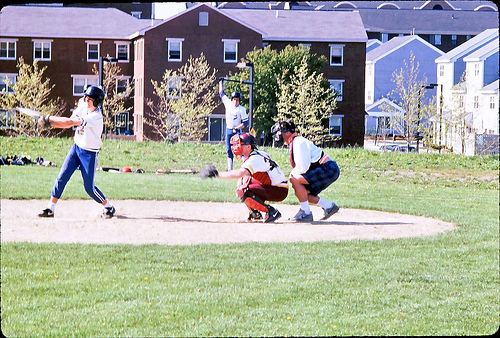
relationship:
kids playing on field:
[39, 77, 339, 222] [0, 136, 499, 337]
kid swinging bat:
[39, 86, 115, 218] [14, 103, 46, 122]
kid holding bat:
[218, 78, 249, 173] [218, 76, 256, 87]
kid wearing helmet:
[39, 86, 115, 218] [84, 85, 105, 105]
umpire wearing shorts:
[271, 121, 340, 223] [301, 160, 339, 196]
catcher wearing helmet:
[204, 132, 289, 225] [239, 132, 257, 147]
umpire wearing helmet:
[271, 121, 340, 223] [278, 121, 297, 133]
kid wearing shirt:
[39, 86, 115, 218] [73, 97, 103, 150]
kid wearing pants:
[39, 86, 115, 218] [48, 145, 107, 203]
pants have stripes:
[48, 145, 107, 203] [93, 188, 107, 203]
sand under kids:
[0, 199, 462, 246] [39, 77, 339, 222]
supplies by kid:
[0, 149, 197, 176] [218, 78, 249, 173]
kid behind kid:
[218, 78, 249, 173] [39, 86, 115, 218]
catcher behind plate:
[204, 132, 289, 225] [60, 212, 99, 222]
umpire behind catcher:
[271, 121, 340, 223] [204, 132, 289, 225]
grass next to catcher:
[0, 165, 498, 335] [204, 132, 289, 225]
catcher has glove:
[204, 132, 289, 225] [200, 164, 217, 179]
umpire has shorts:
[271, 121, 340, 223] [301, 160, 339, 196]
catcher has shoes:
[204, 132, 289, 225] [247, 207, 282, 223]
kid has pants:
[39, 86, 115, 218] [48, 145, 107, 203]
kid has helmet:
[39, 86, 115, 218] [84, 85, 105, 105]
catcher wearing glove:
[204, 132, 289, 225] [200, 164, 217, 179]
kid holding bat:
[39, 86, 115, 218] [14, 103, 46, 122]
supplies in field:
[0, 149, 197, 176] [0, 136, 499, 337]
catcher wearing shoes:
[204, 132, 289, 225] [247, 207, 282, 223]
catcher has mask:
[204, 132, 289, 225] [230, 134, 243, 159]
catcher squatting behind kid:
[204, 132, 289, 225] [39, 86, 115, 218]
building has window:
[133, 2, 365, 148] [223, 39, 239, 62]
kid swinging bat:
[218, 78, 249, 173] [218, 76, 256, 87]